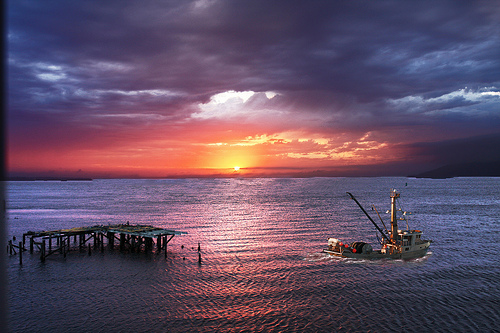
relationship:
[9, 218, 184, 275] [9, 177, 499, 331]
pier standing in water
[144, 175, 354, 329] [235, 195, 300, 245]
reflection on water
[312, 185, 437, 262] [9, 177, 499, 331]
boat on water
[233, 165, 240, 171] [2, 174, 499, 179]
sun on horizon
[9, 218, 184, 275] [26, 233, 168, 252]
pier on support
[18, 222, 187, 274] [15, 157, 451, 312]
wooden pier on water